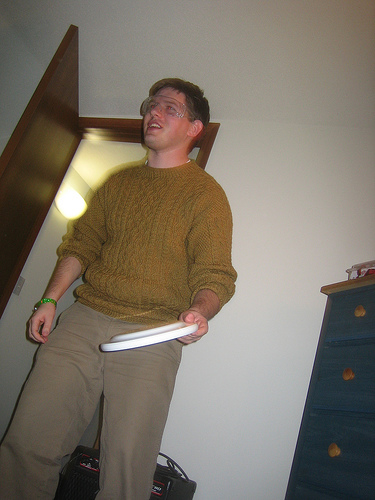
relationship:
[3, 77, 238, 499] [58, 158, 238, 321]
man wearing sweater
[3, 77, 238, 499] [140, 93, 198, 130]
man wearing goggles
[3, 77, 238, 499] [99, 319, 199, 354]
man holding frisbee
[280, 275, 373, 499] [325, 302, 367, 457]
dresser has knobs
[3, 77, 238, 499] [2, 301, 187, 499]
man wearing pants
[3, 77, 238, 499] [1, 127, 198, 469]
man next to doorway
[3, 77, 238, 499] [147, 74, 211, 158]
man has hair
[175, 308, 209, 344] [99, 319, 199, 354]
hand holding frisbee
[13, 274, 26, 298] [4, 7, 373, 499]
switch on wall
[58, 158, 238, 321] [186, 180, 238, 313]
sweater has sleeve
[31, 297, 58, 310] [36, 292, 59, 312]
watch on wrist